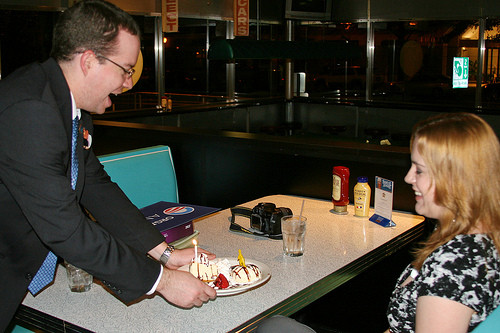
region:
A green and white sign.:
[453, 52, 470, 91]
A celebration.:
[4, 0, 498, 331]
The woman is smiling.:
[404, 112, 497, 234]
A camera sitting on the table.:
[226, 198, 293, 241]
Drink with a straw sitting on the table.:
[280, 197, 311, 255]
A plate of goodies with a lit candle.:
[166, 236, 274, 297]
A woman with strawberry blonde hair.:
[408, 109, 498, 268]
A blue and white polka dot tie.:
[25, 78, 92, 293]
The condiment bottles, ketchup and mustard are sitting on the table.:
[328, 159, 375, 217]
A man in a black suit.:
[0, 3, 165, 328]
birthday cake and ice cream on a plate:
[177, 238, 274, 297]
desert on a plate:
[176, 238, 275, 298]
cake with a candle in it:
[186, 238, 221, 282]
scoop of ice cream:
[226, 248, 262, 283]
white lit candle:
[192, 236, 199, 261]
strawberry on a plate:
[213, 272, 229, 289]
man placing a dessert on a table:
[1, 1, 274, 332]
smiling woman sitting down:
[381, 109, 498, 330]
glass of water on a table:
[281, 197, 311, 257]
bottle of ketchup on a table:
[329, 163, 351, 215]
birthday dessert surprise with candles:
[184, 239, 279, 302]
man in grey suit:
[6, 4, 178, 331]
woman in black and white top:
[370, 115, 496, 331]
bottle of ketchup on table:
[324, 163, 352, 218]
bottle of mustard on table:
[350, 177, 380, 219]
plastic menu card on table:
[372, 171, 402, 233]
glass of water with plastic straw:
[277, 201, 309, 260]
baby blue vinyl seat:
[105, 138, 198, 211]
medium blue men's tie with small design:
[27, 109, 80, 300]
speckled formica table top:
[14, 151, 419, 329]